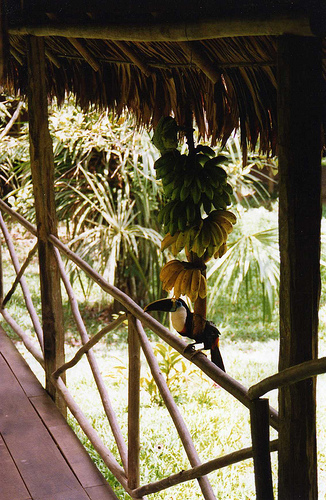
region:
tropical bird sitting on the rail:
[142, 296, 225, 367]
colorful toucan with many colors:
[139, 295, 235, 374]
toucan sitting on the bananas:
[142, 296, 228, 373]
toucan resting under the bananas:
[144, 296, 223, 369]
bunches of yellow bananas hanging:
[159, 210, 237, 300]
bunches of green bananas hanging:
[149, 145, 235, 234]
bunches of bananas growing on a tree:
[152, 144, 236, 300]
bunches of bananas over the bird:
[153, 143, 234, 299]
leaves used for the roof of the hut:
[0, 1, 324, 163]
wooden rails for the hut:
[0, 199, 297, 499]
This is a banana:
[124, 101, 256, 396]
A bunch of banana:
[156, 255, 219, 304]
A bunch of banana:
[200, 205, 236, 261]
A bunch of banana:
[150, 225, 203, 262]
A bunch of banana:
[142, 197, 204, 239]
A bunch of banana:
[195, 150, 241, 216]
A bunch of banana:
[149, 153, 202, 201]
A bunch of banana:
[149, 110, 200, 151]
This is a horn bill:
[131, 291, 249, 382]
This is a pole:
[18, 42, 84, 435]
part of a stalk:
[194, 148, 210, 169]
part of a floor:
[55, 471, 69, 484]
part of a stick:
[128, 428, 166, 475]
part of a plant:
[149, 426, 169, 451]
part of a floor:
[29, 448, 52, 480]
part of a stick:
[123, 384, 148, 431]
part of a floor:
[23, 423, 60, 460]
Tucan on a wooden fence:
[136, 286, 234, 374]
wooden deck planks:
[0, 381, 91, 496]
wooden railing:
[64, 252, 139, 482]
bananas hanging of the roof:
[146, 125, 236, 294]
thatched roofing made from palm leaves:
[1, 2, 325, 105]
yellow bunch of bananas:
[154, 256, 217, 302]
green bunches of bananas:
[156, 150, 236, 227]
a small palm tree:
[234, 215, 285, 319]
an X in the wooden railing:
[46, 234, 139, 479]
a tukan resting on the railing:
[143, 291, 234, 372]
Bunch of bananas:
[147, 121, 230, 299]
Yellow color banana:
[159, 262, 211, 297]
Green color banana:
[153, 154, 241, 202]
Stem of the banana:
[191, 304, 209, 337]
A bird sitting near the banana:
[134, 295, 235, 378]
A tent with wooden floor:
[8, 6, 305, 484]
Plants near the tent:
[79, 116, 144, 253]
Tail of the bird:
[211, 345, 226, 378]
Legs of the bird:
[179, 341, 204, 365]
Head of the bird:
[135, 294, 186, 317]